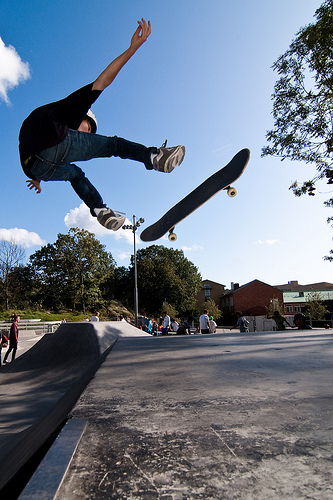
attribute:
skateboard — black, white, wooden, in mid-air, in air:
[141, 147, 251, 243]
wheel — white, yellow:
[167, 232, 179, 243]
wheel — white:
[228, 188, 237, 198]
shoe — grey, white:
[153, 141, 187, 174]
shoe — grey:
[97, 208, 126, 231]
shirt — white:
[200, 315, 210, 331]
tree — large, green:
[26, 227, 116, 311]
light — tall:
[138, 217, 148, 224]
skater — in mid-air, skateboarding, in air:
[19, 19, 186, 231]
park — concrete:
[0, 314, 332, 500]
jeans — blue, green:
[22, 130, 161, 218]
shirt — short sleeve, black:
[17, 82, 101, 159]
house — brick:
[197, 280, 245, 302]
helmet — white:
[86, 110, 100, 133]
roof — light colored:
[282, 290, 333, 304]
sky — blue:
[2, 0, 332, 286]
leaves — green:
[32, 227, 113, 316]